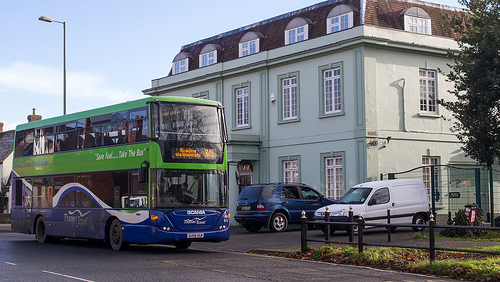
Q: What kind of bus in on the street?
A: A double decker bus.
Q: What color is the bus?
A: Green and blue.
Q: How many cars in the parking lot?
A: Two.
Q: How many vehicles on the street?
A: One.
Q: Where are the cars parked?
A: Parking lot.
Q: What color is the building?
A: Green.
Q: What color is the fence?
A: Black.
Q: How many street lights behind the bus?
A: One.